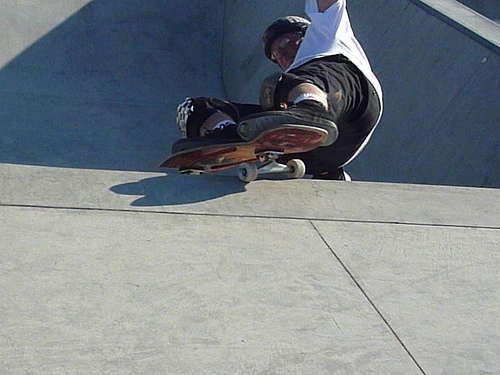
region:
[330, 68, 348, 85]
man wearing black pants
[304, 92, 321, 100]
man wearing white socks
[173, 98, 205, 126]
kneepad on left knee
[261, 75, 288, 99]
kneepad on right knee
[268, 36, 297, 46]
man wearing clear glasses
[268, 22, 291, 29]
man wearing black helmet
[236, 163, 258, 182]
wheel on left of board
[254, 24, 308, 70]
man face looking down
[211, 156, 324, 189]
white wheels on the skate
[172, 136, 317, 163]
bottom of a skateboard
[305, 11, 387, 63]
white shirt on boy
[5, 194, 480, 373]
ramp is gray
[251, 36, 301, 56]
glasses on the face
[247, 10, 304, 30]
black helmet on the head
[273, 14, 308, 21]
white lettering on the side of helmet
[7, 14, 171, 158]
blue wall in the back of person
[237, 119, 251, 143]
hole in bottom of shoe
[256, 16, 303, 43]
Person wearing helmet on head.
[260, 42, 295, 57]
Person wearing glasses on face.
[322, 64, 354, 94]
Person wearing black shorts.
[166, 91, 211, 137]
Person wearing black and white knee pad.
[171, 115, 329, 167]
Person standing on skateboard.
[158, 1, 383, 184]
a man is on a skateboard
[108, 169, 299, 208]
shadow of a skateboard on the ground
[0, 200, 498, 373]
lines in cement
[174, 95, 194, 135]
black and white checkered knee pad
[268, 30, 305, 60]
eyeglasses on a man's eyes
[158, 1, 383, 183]
skateboarders arms are up for balance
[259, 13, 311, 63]
black helmet on man's head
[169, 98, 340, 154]
black skateboarding shoes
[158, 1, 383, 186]
skateboarding is doing a trick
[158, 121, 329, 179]
red and yellow skateboard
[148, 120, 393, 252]
skateboard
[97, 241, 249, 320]
cement wall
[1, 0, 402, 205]
skater at the skate park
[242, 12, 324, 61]
skater wearing glasses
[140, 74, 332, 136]
knee pads on skater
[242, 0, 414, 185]
skater wearing white shirt while skating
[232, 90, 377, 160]
skate shoes